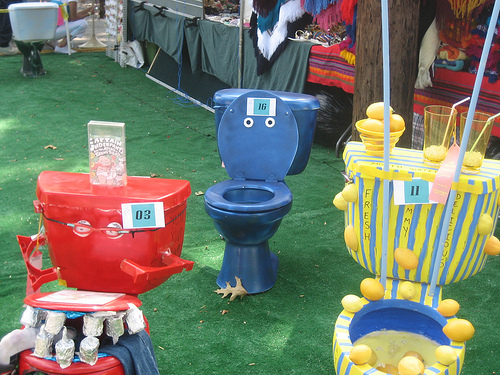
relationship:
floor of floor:
[173, 302, 328, 374] [173, 275, 345, 374]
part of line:
[121, 60, 185, 98] [135, 67, 229, 142]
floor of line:
[173, 302, 328, 374] [135, 67, 229, 142]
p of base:
[192, 241, 280, 299] [208, 202, 304, 309]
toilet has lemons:
[308, 91, 486, 374] [354, 90, 421, 166]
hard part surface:
[42, 171, 197, 199] [37, 179, 166, 201]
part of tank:
[51, 199, 189, 253] [38, 206, 180, 291]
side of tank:
[159, 205, 187, 279] [38, 206, 180, 291]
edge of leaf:
[218, 290, 241, 303] [207, 273, 244, 308]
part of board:
[105, 0, 218, 24] [77, 0, 221, 42]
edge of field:
[4, 44, 113, 86] [0, 50, 116, 200]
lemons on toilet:
[354, 90, 421, 166] [308, 91, 486, 374]